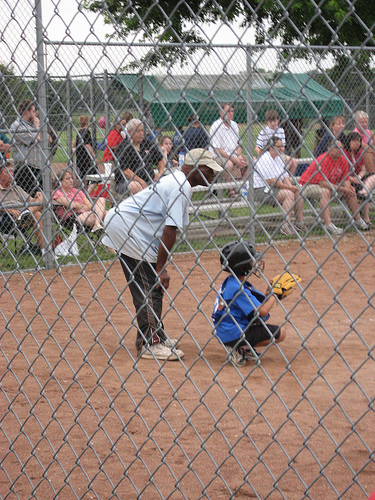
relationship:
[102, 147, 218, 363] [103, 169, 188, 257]
man wears shirt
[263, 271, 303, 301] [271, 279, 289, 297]
glove on hand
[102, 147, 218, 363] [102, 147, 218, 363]
man play man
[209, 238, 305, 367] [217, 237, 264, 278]
boy wears helmet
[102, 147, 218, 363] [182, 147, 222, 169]
man wears cap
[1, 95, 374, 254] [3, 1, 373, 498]
people behind fence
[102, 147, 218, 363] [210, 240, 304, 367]
man behind boy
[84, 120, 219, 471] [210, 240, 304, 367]
man standing behind boy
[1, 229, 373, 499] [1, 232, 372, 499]
dirt on ground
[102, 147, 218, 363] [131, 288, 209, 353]
man wearing jogging pants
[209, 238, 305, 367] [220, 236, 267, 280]
boy wearing helmet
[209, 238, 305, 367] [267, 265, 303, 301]
boy wearing glove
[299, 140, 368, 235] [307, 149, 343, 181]
man wearing shirt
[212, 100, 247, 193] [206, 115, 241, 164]
man wearing shirt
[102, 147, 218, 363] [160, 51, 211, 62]
man standing behind wall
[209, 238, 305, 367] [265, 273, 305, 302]
boy wearing glove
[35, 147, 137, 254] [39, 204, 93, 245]
woman sitting on chair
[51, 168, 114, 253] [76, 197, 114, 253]
woman crossing legs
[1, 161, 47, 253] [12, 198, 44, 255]
man crossing legs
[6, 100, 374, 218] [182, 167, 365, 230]
spectators sitting on bleachers